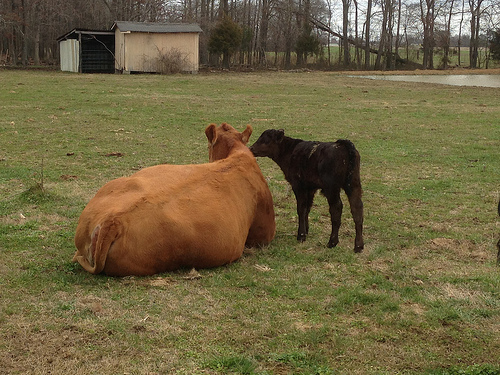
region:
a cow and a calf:
[18, 80, 375, 297]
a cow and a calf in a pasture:
[7, 71, 488, 356]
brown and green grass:
[3, 276, 497, 364]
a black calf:
[247, 123, 376, 254]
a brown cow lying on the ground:
[48, 113, 278, 288]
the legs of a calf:
[291, 181, 369, 256]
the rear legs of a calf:
[323, 189, 370, 257]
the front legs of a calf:
[286, 183, 316, 246]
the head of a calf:
[246, 121, 278, 165]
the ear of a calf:
[275, 128, 285, 143]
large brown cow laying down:
[70, 120, 277, 278]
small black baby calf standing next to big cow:
[249, 126, 365, 251]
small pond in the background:
[344, 72, 499, 89]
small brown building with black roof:
[110, 20, 202, 74]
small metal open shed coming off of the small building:
[56, 25, 113, 72]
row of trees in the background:
[0, 0, 498, 70]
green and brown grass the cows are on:
[1, 69, 498, 374]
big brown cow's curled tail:
[75, 218, 120, 275]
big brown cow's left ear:
[202, 122, 219, 146]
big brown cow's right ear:
[238, 123, 254, 143]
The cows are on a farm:
[35, 7, 456, 352]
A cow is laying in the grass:
[21, 6, 466, 347]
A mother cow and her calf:
[31, 35, 462, 358]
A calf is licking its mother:
[20, 35, 467, 350]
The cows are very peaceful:
[0, 48, 490, 348]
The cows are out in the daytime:
[21, 15, 482, 335]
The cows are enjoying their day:
[22, 53, 459, 351]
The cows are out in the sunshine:
[25, 47, 480, 363]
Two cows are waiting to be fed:
[20, 60, 480, 341]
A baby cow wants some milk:
[30, 53, 475, 342]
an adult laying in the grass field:
[66, 94, 280, 286]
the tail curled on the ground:
[74, 223, 129, 275]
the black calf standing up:
[248, 123, 365, 258]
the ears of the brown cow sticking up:
[202, 115, 252, 150]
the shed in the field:
[110, 17, 200, 75]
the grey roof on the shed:
[114, 19, 200, 35]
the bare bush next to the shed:
[145, 46, 197, 78]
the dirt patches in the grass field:
[54, 139, 128, 186]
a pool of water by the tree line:
[340, 64, 497, 99]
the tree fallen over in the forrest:
[311, 13, 426, 73]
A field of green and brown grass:
[1, 65, 497, 374]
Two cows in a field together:
[62, 120, 373, 275]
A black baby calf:
[245, 127, 375, 252]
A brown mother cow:
[72, 122, 270, 271]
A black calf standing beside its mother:
[71, 120, 373, 276]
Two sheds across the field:
[57, 20, 204, 74]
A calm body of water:
[348, 71, 497, 91]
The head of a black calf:
[250, 125, 281, 160]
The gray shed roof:
[111, 20, 204, 33]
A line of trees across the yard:
[225, 2, 494, 69]